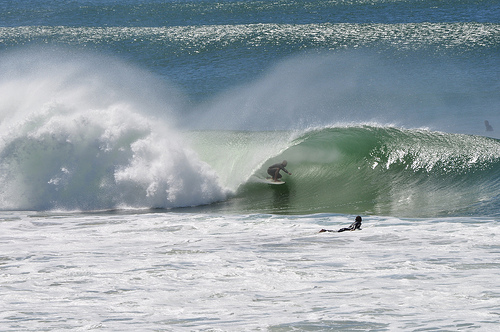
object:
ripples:
[409, 260, 444, 280]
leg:
[266, 167, 279, 180]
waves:
[0, 22, 499, 228]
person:
[257, 156, 293, 183]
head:
[351, 216, 363, 223]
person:
[480, 118, 491, 132]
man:
[266, 158, 291, 183]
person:
[320, 214, 365, 233]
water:
[18, 2, 496, 325]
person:
[315, 215, 362, 235]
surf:
[0, 213, 497, 330]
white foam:
[59, 119, 167, 329]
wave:
[11, 100, 478, 221]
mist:
[12, 46, 172, 121]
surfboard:
[260, 176, 287, 186]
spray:
[38, 37, 168, 130]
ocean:
[80, 28, 427, 252]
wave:
[233, 119, 499, 206]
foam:
[0, 211, 498, 330]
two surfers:
[263, 157, 365, 234]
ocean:
[18, 39, 497, 325]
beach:
[29, 109, 483, 294]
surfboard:
[316, 228, 359, 237]